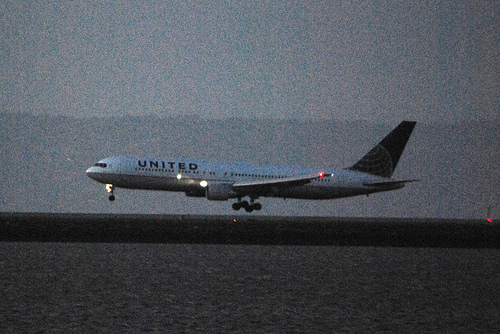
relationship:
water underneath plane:
[146, 277, 289, 316] [71, 97, 448, 234]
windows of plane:
[133, 165, 283, 181] [54, 116, 449, 223]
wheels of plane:
[104, 188, 118, 204] [81, 118, 418, 213]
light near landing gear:
[103, 183, 115, 193] [103, 185, 115, 201]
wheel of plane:
[231, 199, 238, 211] [81, 118, 418, 213]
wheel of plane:
[238, 197, 248, 207] [81, 118, 418, 213]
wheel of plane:
[243, 204, 256, 214] [81, 118, 418, 213]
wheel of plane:
[251, 200, 264, 212] [81, 118, 418, 213]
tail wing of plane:
[345, 119, 415, 177] [17, 80, 467, 250]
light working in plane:
[196, 179, 212, 187] [81, 118, 418, 213]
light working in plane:
[175, 173, 183, 181] [81, 118, 418, 213]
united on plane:
[136, 159, 196, 169] [81, 118, 418, 213]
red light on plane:
[317, 170, 327, 176] [81, 118, 418, 213]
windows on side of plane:
[133, 164, 331, 182] [81, 118, 418, 213]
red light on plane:
[317, 170, 327, 176] [76, 114, 439, 216]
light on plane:
[196, 175, 212, 187] [76, 114, 439, 216]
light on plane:
[170, 167, 185, 184] [76, 114, 439, 216]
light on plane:
[101, 176, 121, 195] [76, 114, 439, 216]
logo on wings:
[361, 141, 397, 182] [337, 110, 427, 192]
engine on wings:
[200, 183, 238, 202] [225, 149, 337, 208]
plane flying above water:
[81, 118, 418, 213] [0, 238, 499, 333]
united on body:
[136, 157, 196, 175] [84, 121, 423, 209]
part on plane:
[341, 117, 418, 176] [81, 118, 418, 213]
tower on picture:
[471, 191, 497, 226] [1, 3, 497, 328]